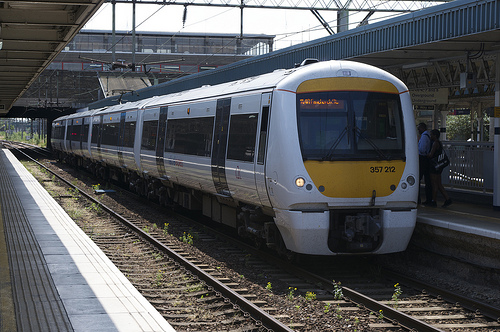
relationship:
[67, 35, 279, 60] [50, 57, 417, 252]
overpass above train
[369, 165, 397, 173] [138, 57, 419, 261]
black numbers on train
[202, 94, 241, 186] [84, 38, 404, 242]
doors on train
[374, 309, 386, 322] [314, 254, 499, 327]
plant growing on tracks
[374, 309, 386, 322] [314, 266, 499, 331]
plant growing on tracks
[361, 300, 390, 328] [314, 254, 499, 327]
plant growing on tracks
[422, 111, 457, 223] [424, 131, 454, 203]
man next to person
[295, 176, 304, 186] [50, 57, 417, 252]
light on train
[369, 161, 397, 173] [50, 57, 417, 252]
black numbers printed on train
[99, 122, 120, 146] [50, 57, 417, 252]
windows on side of train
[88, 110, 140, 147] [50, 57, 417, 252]
windows on side of train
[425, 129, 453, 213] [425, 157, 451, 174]
person c carrying a bag